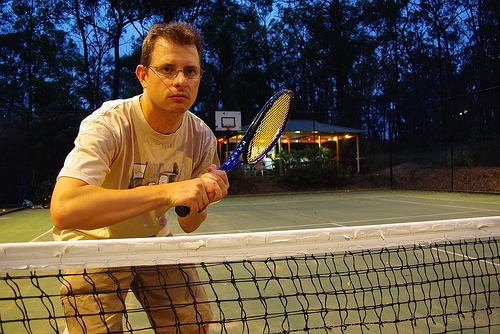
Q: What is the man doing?
A: Playing.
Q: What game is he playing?
A: Tennis.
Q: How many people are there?
A: One.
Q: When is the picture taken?
A: Nighttime.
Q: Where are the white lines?
A: In the ground.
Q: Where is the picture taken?
A: At a tennis court.